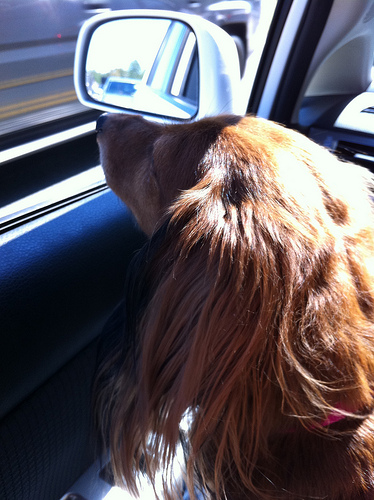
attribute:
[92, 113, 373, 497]
dog — brown, black, having fun, joyriding, entertaining himself, loving the ride, enjoying car ride, hairy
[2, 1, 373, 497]
car — white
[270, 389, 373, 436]
colar — pink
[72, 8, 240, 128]
mirror — concave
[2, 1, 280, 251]
window — open, clear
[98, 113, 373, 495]
hair — brown, black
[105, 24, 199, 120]
door — closed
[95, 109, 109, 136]
nose — black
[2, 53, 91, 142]
road — yellow, tarmac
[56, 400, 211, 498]
car seat — grey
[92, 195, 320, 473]
ear — hairy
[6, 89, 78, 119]
pole — yellow